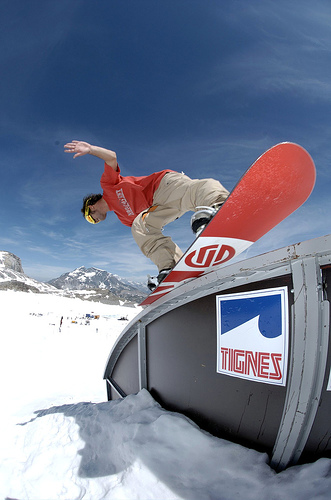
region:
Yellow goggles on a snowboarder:
[77, 203, 103, 232]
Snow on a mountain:
[31, 434, 144, 495]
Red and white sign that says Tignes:
[215, 331, 299, 392]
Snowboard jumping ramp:
[92, 254, 325, 468]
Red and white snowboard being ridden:
[151, 134, 312, 317]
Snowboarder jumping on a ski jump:
[48, 135, 306, 304]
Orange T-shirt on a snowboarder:
[56, 162, 183, 235]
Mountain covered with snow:
[38, 264, 141, 315]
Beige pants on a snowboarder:
[113, 189, 250, 273]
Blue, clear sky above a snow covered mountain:
[27, 122, 224, 263]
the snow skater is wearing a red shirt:
[99, 140, 175, 232]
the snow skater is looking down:
[67, 134, 301, 323]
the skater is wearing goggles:
[83, 203, 101, 227]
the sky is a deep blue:
[0, 2, 326, 295]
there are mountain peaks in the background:
[2, 248, 154, 312]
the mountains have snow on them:
[1, 250, 154, 323]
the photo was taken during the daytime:
[3, 0, 328, 497]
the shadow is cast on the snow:
[19, 390, 326, 498]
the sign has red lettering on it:
[212, 284, 298, 388]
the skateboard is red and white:
[143, 141, 310, 310]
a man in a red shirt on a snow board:
[60, 134, 306, 302]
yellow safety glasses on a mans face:
[78, 193, 93, 220]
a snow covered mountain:
[44, 262, 137, 302]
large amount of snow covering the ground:
[18, 299, 113, 335]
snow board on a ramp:
[99, 232, 324, 460]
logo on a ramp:
[212, 283, 287, 389]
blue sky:
[151, 66, 327, 138]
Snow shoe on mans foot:
[186, 202, 225, 234]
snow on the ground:
[22, 386, 325, 493]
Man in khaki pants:
[127, 167, 229, 271]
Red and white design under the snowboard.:
[181, 237, 244, 272]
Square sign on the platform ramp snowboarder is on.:
[216, 295, 286, 380]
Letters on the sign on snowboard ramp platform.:
[219, 346, 284, 378]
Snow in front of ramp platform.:
[1, 410, 304, 499]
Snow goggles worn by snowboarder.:
[76, 197, 111, 229]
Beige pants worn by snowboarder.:
[117, 179, 228, 258]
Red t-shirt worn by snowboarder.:
[92, 169, 164, 220]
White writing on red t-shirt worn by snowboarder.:
[114, 187, 137, 219]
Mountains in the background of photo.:
[2, 242, 160, 306]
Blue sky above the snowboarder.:
[2, 2, 315, 239]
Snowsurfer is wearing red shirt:
[44, 115, 240, 300]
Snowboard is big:
[125, 136, 322, 310]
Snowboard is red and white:
[127, 130, 325, 313]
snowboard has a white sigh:
[179, 238, 236, 272]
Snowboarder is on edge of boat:
[53, 116, 313, 307]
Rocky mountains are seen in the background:
[0, 244, 144, 303]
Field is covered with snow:
[7, 285, 327, 495]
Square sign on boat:
[208, 285, 293, 388]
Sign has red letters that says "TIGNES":
[203, 277, 303, 391]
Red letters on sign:
[208, 343, 290, 386]